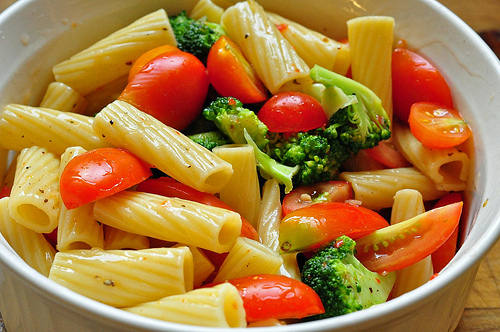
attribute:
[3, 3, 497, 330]
bowl — white, side  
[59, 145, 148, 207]
tomato — red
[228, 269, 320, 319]
tomato — red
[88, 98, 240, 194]
noodle — yellow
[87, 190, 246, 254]
noodle — yellow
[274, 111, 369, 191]
broccoli — green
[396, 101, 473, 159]
tomato half — small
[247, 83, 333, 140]
tomato half — small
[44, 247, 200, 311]
noodle — rigatoni, white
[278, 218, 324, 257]
tip — green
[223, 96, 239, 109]
pepper flake — red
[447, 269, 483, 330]
counter top — brown, laminate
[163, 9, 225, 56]
broccoli floret — dark, green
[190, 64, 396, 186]
broccoli — green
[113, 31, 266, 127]
tomatoes — sliced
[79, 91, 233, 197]
noodle — off white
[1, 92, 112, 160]
noodle — off white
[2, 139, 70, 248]
noodle — off white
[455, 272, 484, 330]
table — wooden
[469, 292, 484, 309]
spot — dark 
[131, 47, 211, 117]
tomato — moisture, Red 